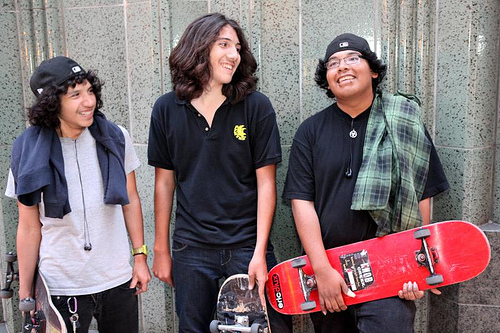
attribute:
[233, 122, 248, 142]
logo — yellow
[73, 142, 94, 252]
ear buds — black, dangling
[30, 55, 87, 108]
baseball hat — black, backwards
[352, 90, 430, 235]
shirt — green, blue, plaid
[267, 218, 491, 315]
skateboard — red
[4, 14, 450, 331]
boys — teenagers, standing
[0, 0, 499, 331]
wall — gray, black, shiny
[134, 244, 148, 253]
watch — wide band, yellow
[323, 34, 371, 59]
cap — backwards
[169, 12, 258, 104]
hair — shoulder length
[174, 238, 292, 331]
denim jeans — dark wash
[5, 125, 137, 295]
shirt — white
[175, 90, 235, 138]
collar — unbuttoned